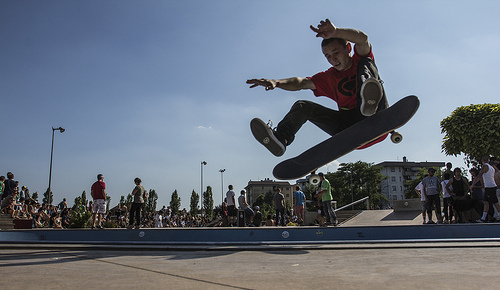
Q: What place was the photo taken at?
A: It was taken at the skate park.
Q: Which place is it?
A: It is a skate park.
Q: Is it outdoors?
A: Yes, it is outdoors.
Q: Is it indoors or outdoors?
A: It is outdoors.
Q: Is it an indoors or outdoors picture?
A: It is outdoors.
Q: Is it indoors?
A: No, it is outdoors.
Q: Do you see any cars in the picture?
A: No, there are no cars.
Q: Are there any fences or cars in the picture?
A: No, there are no cars or fences.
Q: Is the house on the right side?
A: Yes, the house is on the right of the image.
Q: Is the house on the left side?
A: No, the house is on the right of the image.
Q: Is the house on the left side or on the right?
A: The house is on the right of the image.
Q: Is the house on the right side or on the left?
A: The house is on the right of the image.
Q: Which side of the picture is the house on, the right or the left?
A: The house is on the right of the image.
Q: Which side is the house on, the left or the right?
A: The house is on the right of the image.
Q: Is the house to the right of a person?
A: Yes, the house is to the right of a person.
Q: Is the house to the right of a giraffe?
A: No, the house is to the right of a person.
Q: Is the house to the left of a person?
A: No, the house is to the right of a person.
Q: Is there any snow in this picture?
A: Yes, there is snow.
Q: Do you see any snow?
A: Yes, there is snow.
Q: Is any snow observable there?
A: Yes, there is snow.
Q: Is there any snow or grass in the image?
A: Yes, there is snow.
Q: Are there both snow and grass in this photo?
A: No, there is snow but no grass.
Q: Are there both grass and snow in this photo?
A: No, there is snow but no grass.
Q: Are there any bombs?
A: No, there are no bombs.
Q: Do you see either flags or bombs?
A: No, there are no bombs or flags.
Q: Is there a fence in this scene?
A: No, there are no fences.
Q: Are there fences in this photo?
A: No, there are no fences.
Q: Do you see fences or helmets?
A: No, there are no fences or helmets.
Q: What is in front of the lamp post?
A: The skate park is in front of the lamp post.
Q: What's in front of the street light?
A: The skate park is in front of the lamp post.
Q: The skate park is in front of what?
A: The skate park is in front of the street lamp.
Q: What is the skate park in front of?
A: The skate park is in front of the street lamp.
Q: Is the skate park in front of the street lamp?
A: Yes, the skate park is in front of the street lamp.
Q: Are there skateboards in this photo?
A: Yes, there is a skateboard.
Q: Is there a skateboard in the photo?
A: Yes, there is a skateboard.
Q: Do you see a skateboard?
A: Yes, there is a skateboard.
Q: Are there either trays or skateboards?
A: Yes, there is a skateboard.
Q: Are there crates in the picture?
A: No, there are no crates.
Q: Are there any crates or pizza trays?
A: No, there are no crates or pizza trays.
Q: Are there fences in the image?
A: No, there are no fences.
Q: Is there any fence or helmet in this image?
A: No, there are no fences or helmets.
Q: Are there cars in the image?
A: No, there are no cars.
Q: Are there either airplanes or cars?
A: No, there are no cars or airplanes.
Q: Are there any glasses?
A: No, there are no glasses.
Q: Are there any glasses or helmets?
A: No, there are no glasses or helmets.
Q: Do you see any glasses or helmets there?
A: No, there are no glasses or helmets.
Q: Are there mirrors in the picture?
A: No, there are no mirrors.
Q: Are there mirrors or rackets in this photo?
A: No, there are no mirrors or rackets.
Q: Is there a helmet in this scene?
A: No, there are no helmets.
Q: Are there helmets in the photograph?
A: No, there are no helmets.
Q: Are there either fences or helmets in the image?
A: No, there are no helmets or fences.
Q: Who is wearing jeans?
A: The man is wearing jeans.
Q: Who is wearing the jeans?
A: The man is wearing jeans.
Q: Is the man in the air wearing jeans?
A: Yes, the man is wearing jeans.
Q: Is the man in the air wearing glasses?
A: No, the man is wearing jeans.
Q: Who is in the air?
A: The man is in the air.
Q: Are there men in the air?
A: Yes, there is a man in the air.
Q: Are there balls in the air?
A: No, there is a man in the air.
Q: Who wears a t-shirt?
A: The man wears a t-shirt.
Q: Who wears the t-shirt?
A: The man wears a t-shirt.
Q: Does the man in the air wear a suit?
A: No, the man wears a tee shirt.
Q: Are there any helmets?
A: No, there are no helmets.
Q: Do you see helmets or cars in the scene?
A: No, there are no helmets or cars.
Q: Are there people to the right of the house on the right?
A: No, the person is to the left of the house.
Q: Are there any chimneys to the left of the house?
A: No, there is a person to the left of the house.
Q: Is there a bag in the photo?
A: No, there are no bags.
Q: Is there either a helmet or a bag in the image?
A: No, there are no bags or helmets.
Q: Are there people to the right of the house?
A: No, the person is to the left of the house.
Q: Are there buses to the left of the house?
A: No, there is a person to the left of the house.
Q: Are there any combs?
A: No, there are no combs.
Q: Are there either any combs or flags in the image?
A: No, there are no combs or flags.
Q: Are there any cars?
A: No, there are no cars.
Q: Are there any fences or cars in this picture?
A: No, there are no cars or fences.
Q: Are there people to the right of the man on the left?
A: Yes, there is a person to the right of the man.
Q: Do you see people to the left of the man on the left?
A: No, the person is to the right of the man.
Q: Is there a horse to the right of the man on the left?
A: No, there is a person to the right of the man.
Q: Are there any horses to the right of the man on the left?
A: No, there is a person to the right of the man.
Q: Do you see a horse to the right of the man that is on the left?
A: No, there is a person to the right of the man.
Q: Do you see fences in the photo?
A: No, there are no fences.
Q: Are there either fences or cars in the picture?
A: No, there are no fences or cars.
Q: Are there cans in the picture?
A: No, there are no cans.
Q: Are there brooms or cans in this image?
A: No, there are no cans or brooms.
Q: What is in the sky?
A: The clouds are in the sky.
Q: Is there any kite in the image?
A: No, there are no kites.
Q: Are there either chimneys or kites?
A: No, there are no kites or chimneys.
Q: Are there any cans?
A: No, there are no cans.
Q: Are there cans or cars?
A: No, there are no cans or cars.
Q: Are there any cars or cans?
A: No, there are no cans or cars.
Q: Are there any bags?
A: No, there are no bags.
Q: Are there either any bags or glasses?
A: No, there are no bags or glasses.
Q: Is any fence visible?
A: No, there are no fences.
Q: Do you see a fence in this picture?
A: No, there are no fences.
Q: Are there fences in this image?
A: No, there are no fences.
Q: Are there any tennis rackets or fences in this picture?
A: No, there are no fences or tennis rackets.